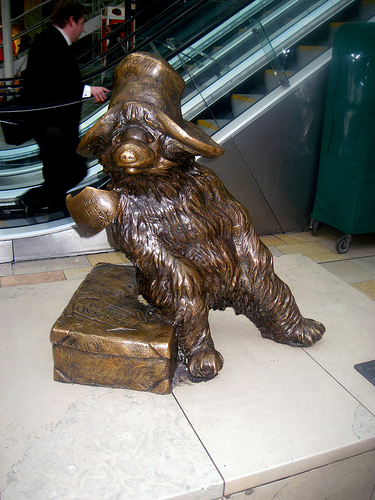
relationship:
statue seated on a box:
[67, 61, 330, 386] [47, 258, 184, 395]